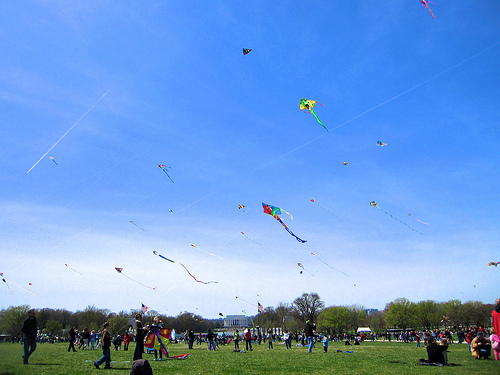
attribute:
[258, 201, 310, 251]
kite — colorful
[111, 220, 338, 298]
kite — colorful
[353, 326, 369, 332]
tent — white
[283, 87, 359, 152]
kite — yellow, green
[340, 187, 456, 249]
kite — colorful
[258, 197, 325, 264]
kite — colorful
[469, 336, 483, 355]
jacket — brown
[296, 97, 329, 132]
kite — colorful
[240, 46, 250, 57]
kite — colorful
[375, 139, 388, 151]
kite — colorful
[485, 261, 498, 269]
kite — colorful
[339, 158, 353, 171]
kite — colorful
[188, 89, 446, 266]
kite — colorful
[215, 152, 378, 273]
kite — green, red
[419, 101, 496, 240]
sky — blue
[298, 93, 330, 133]
kite — yellow, green